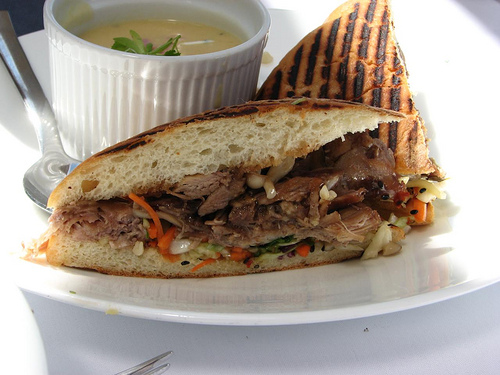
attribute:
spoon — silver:
[0, 9, 82, 211]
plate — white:
[0, 27, 500, 327]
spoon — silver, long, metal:
[0, 6, 88, 216]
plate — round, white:
[3, 1, 483, 327]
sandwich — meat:
[19, 96, 447, 280]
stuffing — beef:
[53, 124, 392, 236]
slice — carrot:
[126, 187, 164, 237]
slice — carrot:
[156, 226, 178, 255]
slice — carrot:
[221, 240, 253, 268]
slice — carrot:
[295, 239, 311, 260]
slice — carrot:
[401, 190, 432, 223]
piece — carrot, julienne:
[127, 190, 165, 240]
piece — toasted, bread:
[41, 91, 410, 213]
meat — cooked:
[52, 137, 399, 247]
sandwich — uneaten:
[30, 93, 412, 278]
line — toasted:
[316, 14, 341, 97]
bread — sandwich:
[253, 0, 434, 177]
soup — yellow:
[84, 4, 209, 49]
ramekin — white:
[33, 2, 268, 156]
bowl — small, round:
[44, 13, 260, 148]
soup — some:
[94, 13, 226, 53]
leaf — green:
[106, 22, 180, 55]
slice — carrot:
[124, 185, 168, 239]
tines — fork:
[120, 347, 184, 372]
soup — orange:
[77, 7, 227, 53]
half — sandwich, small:
[32, 96, 420, 287]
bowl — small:
[36, 1, 258, 142]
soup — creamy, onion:
[89, 12, 219, 46]